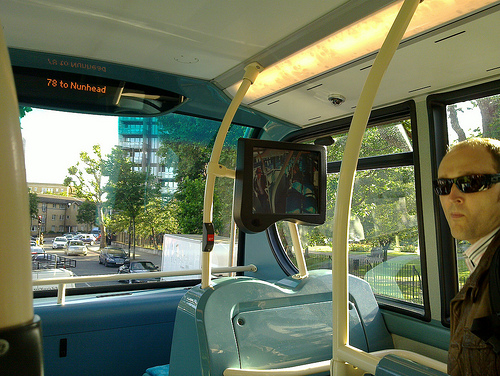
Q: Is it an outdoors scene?
A: Yes, it is outdoors.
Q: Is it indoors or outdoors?
A: It is outdoors.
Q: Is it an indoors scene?
A: No, it is outdoors.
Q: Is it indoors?
A: No, it is outdoors.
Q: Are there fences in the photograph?
A: Yes, there is a fence.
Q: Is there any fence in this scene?
A: Yes, there is a fence.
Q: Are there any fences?
A: Yes, there is a fence.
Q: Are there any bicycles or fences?
A: Yes, there is a fence.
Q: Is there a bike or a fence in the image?
A: Yes, there is a fence.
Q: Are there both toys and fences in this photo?
A: No, there is a fence but no toys.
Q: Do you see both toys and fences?
A: No, there is a fence but no toys.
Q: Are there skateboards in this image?
A: No, there are no skateboards.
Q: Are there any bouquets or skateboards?
A: No, there are no skateboards or bouquets.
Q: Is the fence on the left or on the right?
A: The fence is on the right of the image.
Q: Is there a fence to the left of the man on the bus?
A: Yes, there is a fence to the left of the man.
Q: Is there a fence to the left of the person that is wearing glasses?
A: Yes, there is a fence to the left of the man.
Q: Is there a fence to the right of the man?
A: No, the fence is to the left of the man.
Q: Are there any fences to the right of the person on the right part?
A: No, the fence is to the left of the man.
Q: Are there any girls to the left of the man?
A: No, there is a fence to the left of the man.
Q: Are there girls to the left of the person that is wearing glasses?
A: No, there is a fence to the left of the man.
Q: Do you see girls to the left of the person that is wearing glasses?
A: No, there is a fence to the left of the man.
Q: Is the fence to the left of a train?
A: No, the fence is to the left of the man.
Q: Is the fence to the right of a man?
A: No, the fence is to the left of a man.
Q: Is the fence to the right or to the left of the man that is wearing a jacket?
A: The fence is to the left of the man.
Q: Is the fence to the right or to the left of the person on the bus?
A: The fence is to the left of the man.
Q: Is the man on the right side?
A: Yes, the man is on the right of the image.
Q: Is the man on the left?
A: No, the man is on the right of the image.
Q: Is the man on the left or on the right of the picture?
A: The man is on the right of the image.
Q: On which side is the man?
A: The man is on the right of the image.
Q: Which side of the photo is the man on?
A: The man is on the right of the image.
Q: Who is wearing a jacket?
A: The man is wearing a jacket.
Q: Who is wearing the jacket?
A: The man is wearing a jacket.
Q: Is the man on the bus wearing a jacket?
A: Yes, the man is wearing a jacket.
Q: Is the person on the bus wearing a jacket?
A: Yes, the man is wearing a jacket.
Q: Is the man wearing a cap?
A: No, the man is wearing a jacket.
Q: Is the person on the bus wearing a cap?
A: No, the man is wearing a jacket.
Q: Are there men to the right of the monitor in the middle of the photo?
A: Yes, there is a man to the right of the monitor.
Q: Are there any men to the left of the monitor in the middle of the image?
A: No, the man is to the right of the monitor.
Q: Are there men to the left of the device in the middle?
A: No, the man is to the right of the monitor.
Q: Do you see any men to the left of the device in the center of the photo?
A: No, the man is to the right of the monitor.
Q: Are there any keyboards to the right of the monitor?
A: No, there is a man to the right of the monitor.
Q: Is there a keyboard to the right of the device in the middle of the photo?
A: No, there is a man to the right of the monitor.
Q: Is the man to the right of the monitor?
A: Yes, the man is to the right of the monitor.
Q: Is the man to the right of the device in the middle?
A: Yes, the man is to the right of the monitor.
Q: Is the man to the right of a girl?
A: No, the man is to the right of the monitor.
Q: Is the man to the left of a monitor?
A: No, the man is to the right of a monitor.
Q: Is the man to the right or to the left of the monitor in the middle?
A: The man is to the right of the monitor.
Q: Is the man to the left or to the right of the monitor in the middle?
A: The man is to the right of the monitor.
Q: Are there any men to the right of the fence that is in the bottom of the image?
A: Yes, there is a man to the right of the fence.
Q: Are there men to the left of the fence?
A: No, the man is to the right of the fence.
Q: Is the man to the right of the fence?
A: Yes, the man is to the right of the fence.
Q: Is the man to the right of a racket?
A: No, the man is to the right of the fence.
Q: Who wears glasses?
A: The man wears glasses.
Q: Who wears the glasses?
A: The man wears glasses.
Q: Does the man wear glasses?
A: Yes, the man wears glasses.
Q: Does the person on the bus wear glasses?
A: Yes, the man wears glasses.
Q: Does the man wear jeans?
A: No, the man wears glasses.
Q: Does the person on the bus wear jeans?
A: No, the man wears glasses.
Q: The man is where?
A: The man is on the bus.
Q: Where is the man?
A: The man is on the bus.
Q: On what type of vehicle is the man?
A: The man is on the bus.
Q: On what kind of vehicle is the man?
A: The man is on the bus.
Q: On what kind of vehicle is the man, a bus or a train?
A: The man is on a bus.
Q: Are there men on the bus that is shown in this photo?
A: Yes, there is a man on the bus.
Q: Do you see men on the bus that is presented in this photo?
A: Yes, there is a man on the bus.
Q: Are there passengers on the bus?
A: No, there is a man on the bus.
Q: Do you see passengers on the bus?
A: No, there is a man on the bus.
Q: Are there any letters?
A: Yes, there are letters.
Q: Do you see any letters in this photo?
A: Yes, there are letters.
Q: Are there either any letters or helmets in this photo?
A: Yes, there are letters.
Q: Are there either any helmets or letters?
A: Yes, there are letters.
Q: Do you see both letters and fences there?
A: Yes, there are both letters and a fence.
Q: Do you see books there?
A: No, there are no books.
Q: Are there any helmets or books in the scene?
A: No, there are no books or helmets.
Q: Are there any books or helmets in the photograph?
A: No, there are no books or helmets.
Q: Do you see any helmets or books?
A: No, there are no books or helmets.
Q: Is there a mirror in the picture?
A: Yes, there is a mirror.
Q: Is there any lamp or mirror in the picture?
A: Yes, there is a mirror.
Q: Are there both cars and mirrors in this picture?
A: Yes, there are both a mirror and a car.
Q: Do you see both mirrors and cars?
A: Yes, there are both a mirror and a car.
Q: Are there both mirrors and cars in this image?
A: Yes, there are both a mirror and a car.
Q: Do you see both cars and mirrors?
A: Yes, there are both a mirror and a car.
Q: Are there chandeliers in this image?
A: No, there are no chandeliers.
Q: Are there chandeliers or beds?
A: No, there are no chandeliers or beds.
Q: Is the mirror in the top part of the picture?
A: Yes, the mirror is in the top of the image.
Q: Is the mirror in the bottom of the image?
A: No, the mirror is in the top of the image.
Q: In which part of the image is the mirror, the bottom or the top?
A: The mirror is in the top of the image.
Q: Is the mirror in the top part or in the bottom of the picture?
A: The mirror is in the top of the image.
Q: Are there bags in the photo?
A: No, there are no bags.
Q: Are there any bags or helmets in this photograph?
A: No, there are no bags or helmets.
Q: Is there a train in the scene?
A: No, there are no trains.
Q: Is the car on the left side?
A: Yes, the car is on the left of the image.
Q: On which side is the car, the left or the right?
A: The car is on the left of the image.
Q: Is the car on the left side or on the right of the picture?
A: The car is on the left of the image.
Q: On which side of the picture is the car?
A: The car is on the left of the image.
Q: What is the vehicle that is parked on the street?
A: The vehicle is a car.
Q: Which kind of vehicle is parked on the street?
A: The vehicle is a car.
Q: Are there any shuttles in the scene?
A: No, there are no shuttles.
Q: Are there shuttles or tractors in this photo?
A: No, there are no shuttles or tractors.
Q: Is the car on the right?
A: No, the car is on the left of the image.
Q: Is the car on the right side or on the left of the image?
A: The car is on the left of the image.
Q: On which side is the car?
A: The car is on the left of the image.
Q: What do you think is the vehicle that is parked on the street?
A: The vehicle is a car.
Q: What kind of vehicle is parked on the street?
A: The vehicle is a car.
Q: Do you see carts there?
A: No, there are no carts.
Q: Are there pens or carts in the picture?
A: No, there are no carts or pens.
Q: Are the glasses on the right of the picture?
A: Yes, the glasses are on the right of the image.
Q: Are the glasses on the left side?
A: No, the glasses are on the right of the image.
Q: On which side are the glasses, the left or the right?
A: The glasses are on the right of the image.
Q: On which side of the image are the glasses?
A: The glasses are on the right of the image.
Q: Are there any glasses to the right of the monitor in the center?
A: Yes, there are glasses to the right of the monitor.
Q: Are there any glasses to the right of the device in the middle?
A: Yes, there are glasses to the right of the monitor.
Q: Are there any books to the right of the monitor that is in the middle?
A: No, there are glasses to the right of the monitor.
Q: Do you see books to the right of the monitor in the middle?
A: No, there are glasses to the right of the monitor.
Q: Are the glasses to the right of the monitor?
A: Yes, the glasses are to the right of the monitor.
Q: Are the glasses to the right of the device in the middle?
A: Yes, the glasses are to the right of the monitor.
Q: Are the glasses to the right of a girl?
A: No, the glasses are to the right of the monitor.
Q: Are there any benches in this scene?
A: No, there are no benches.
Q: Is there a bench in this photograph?
A: No, there are no benches.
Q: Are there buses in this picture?
A: Yes, there is a bus.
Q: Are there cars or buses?
A: Yes, there is a bus.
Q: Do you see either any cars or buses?
A: Yes, there is a bus.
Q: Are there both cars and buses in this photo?
A: Yes, there are both a bus and a car.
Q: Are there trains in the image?
A: No, there are no trains.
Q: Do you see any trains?
A: No, there are no trains.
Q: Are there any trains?
A: No, there are no trains.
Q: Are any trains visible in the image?
A: No, there are no trains.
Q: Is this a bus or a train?
A: This is a bus.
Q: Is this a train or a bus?
A: This is a bus.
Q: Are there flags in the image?
A: No, there are no flags.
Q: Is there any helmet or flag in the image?
A: No, there are no flags or helmets.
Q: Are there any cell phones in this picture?
A: No, there are no cell phones.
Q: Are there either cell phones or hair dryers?
A: No, there are no cell phones or hair dryers.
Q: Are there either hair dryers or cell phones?
A: No, there are no cell phones or hair dryers.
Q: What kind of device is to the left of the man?
A: The device is a monitor.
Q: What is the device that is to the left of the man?
A: The device is a monitor.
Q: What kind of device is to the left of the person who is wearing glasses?
A: The device is a monitor.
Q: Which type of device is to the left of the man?
A: The device is a monitor.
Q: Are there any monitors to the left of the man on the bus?
A: Yes, there is a monitor to the left of the man.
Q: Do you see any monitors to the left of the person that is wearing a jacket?
A: Yes, there is a monitor to the left of the man.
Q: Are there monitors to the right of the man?
A: No, the monitor is to the left of the man.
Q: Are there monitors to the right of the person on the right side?
A: No, the monitor is to the left of the man.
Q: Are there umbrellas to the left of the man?
A: No, there is a monitor to the left of the man.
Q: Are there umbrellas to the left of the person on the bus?
A: No, there is a monitor to the left of the man.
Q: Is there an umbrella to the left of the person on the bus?
A: No, there is a monitor to the left of the man.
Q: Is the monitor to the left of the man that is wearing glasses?
A: Yes, the monitor is to the left of the man.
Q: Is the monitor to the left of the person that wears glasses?
A: Yes, the monitor is to the left of the man.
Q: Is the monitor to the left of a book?
A: No, the monitor is to the left of the man.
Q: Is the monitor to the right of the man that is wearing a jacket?
A: No, the monitor is to the left of the man.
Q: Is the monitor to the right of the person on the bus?
A: No, the monitor is to the left of the man.